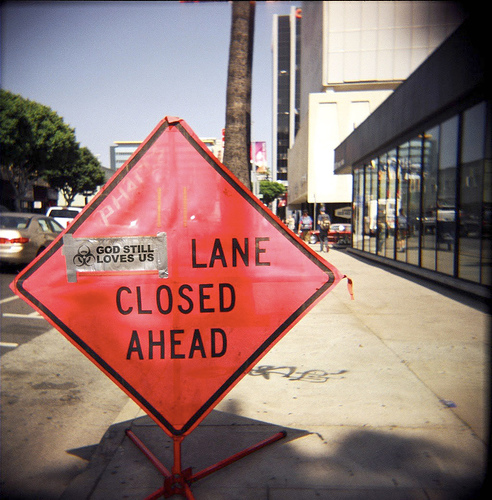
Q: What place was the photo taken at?
A: It was taken at the sidewalk.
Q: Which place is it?
A: It is a sidewalk.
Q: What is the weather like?
A: It is clear.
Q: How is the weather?
A: It is clear.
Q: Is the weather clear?
A: Yes, it is clear.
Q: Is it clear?
A: Yes, it is clear.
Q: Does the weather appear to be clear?
A: Yes, it is clear.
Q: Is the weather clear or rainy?
A: It is clear.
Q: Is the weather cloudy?
A: No, it is clear.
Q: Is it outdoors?
A: Yes, it is outdoors.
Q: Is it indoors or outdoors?
A: It is outdoors.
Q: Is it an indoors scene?
A: No, it is outdoors.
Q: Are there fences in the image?
A: No, there are no fences.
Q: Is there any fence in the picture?
A: No, there are no fences.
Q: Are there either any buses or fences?
A: No, there are no fences or buses.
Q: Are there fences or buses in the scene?
A: No, there are no fences or buses.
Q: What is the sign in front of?
A: The sign is in front of the trunk.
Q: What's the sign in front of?
A: The sign is in front of the trunk.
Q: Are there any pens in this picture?
A: No, there are no pens.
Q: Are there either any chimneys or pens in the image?
A: No, there are no pens or chimneys.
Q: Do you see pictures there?
A: No, there are no pictures.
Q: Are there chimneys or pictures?
A: No, there are no pictures or chimneys.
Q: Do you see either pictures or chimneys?
A: No, there are no pictures or chimneys.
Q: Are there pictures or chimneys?
A: No, there are no pictures or chimneys.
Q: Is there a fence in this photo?
A: No, there are no fences.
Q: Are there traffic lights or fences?
A: No, there are no fences or traffic lights.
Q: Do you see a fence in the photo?
A: No, there are no fences.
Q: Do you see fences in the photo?
A: No, there are no fences.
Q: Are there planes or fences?
A: No, there are no fences or planes.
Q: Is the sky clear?
A: Yes, the sky is clear.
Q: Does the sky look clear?
A: Yes, the sky is clear.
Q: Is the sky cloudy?
A: No, the sky is clear.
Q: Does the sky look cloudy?
A: No, the sky is clear.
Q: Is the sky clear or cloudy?
A: The sky is clear.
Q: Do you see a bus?
A: No, there are no buses.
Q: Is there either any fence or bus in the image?
A: No, there are no buses or fences.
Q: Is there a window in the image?
A: Yes, there are windows.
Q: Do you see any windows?
A: Yes, there are windows.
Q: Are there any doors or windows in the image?
A: Yes, there are windows.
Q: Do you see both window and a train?
A: No, there are windows but no trains.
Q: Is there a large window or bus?
A: Yes, there are large windows.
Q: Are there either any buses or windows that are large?
A: Yes, the windows are large.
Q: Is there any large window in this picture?
A: Yes, there are large windows.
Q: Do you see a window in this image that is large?
A: Yes, there are windows that are large.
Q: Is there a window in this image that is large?
A: Yes, there are windows that are large.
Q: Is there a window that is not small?
A: Yes, there are large windows.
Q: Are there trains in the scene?
A: No, there are no trains.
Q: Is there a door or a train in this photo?
A: No, there are no trains or doors.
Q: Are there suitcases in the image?
A: No, there are no suitcases.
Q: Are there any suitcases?
A: No, there are no suitcases.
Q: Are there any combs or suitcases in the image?
A: No, there are no suitcases or combs.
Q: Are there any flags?
A: No, there are no flags.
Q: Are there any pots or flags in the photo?
A: No, there are no flags or pots.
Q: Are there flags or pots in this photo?
A: No, there are no flags or pots.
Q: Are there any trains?
A: No, there are no trains.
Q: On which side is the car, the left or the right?
A: The car is on the left of the image.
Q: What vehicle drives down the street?
A: The vehicle is a car.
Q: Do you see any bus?
A: No, there are no buses.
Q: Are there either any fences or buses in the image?
A: No, there are no buses or fences.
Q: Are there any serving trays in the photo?
A: No, there are no serving trays.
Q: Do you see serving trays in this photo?
A: No, there are no serving trays.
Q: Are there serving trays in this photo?
A: No, there are no serving trays.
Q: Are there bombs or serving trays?
A: No, there are no serving trays or bombs.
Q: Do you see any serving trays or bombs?
A: No, there are no serving trays or bombs.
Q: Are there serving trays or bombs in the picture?
A: No, there are no serving trays or bombs.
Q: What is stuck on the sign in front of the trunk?
A: The sticker is stuck on the sign.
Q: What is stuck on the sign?
A: The sticker is stuck on the sign.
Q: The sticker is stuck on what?
A: The sticker is stuck on the sign.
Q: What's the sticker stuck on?
A: The sticker is stuck on the sign.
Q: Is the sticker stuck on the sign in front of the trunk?
A: Yes, the sticker is stuck on the sign.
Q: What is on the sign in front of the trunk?
A: The sticker is on the sign.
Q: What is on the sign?
A: The sticker is on the sign.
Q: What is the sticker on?
A: The sticker is on the sign.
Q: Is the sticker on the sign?
A: Yes, the sticker is on the sign.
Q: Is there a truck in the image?
A: Yes, there is a truck.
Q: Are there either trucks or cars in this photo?
A: Yes, there is a truck.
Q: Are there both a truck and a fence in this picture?
A: No, there is a truck but no fences.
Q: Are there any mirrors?
A: No, there are no mirrors.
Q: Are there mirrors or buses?
A: No, there are no mirrors or buses.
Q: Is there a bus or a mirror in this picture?
A: No, there are no mirrors or buses.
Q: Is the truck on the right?
A: No, the truck is on the left of the image.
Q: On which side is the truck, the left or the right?
A: The truck is on the left of the image.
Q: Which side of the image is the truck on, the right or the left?
A: The truck is on the left of the image.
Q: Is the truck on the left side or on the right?
A: The truck is on the left of the image.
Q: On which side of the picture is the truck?
A: The truck is on the left of the image.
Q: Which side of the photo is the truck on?
A: The truck is on the left of the image.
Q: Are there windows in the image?
A: Yes, there are windows.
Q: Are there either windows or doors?
A: Yes, there are windows.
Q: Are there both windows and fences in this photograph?
A: No, there are windows but no fences.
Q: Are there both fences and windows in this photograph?
A: No, there are windows but no fences.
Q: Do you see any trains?
A: No, there are no trains.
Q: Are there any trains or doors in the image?
A: No, there are no trains or doors.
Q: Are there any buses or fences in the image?
A: No, there are no fences or buses.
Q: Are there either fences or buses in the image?
A: No, there are no fences or buses.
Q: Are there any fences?
A: No, there are no fences.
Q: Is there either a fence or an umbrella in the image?
A: No, there are no fences or umbrellas.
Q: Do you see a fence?
A: No, there are no fences.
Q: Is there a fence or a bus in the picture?
A: No, there are no fences or buses.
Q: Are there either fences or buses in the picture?
A: No, there are no fences or buses.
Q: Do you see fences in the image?
A: No, there are no fences.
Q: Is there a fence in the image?
A: No, there are no fences.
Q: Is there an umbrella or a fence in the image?
A: No, there are no fences or umbrellas.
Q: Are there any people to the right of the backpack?
A: No, the people are to the left of the backpack.